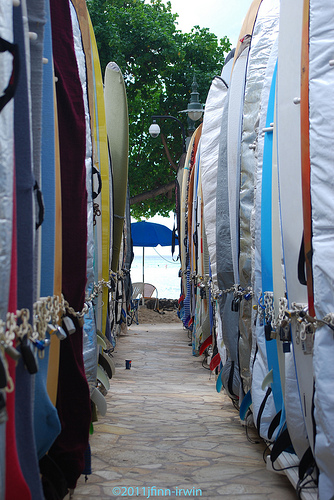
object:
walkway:
[105, 325, 233, 499]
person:
[164, 262, 168, 269]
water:
[131, 255, 180, 299]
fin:
[209, 353, 222, 371]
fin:
[198, 334, 212, 356]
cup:
[125, 358, 132, 369]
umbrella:
[130, 219, 179, 304]